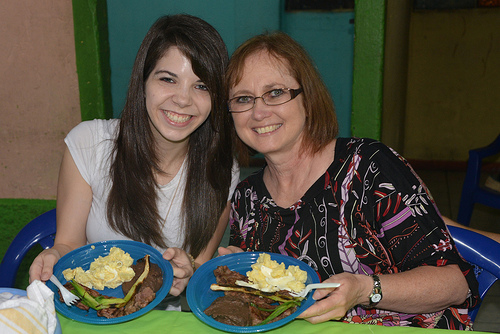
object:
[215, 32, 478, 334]
woman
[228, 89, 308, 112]
eyeglasses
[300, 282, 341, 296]
fork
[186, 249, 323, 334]
plate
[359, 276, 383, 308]
watch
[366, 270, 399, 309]
wrist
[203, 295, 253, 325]
food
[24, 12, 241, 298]
woman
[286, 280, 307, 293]
potatoes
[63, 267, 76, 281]
potatoes